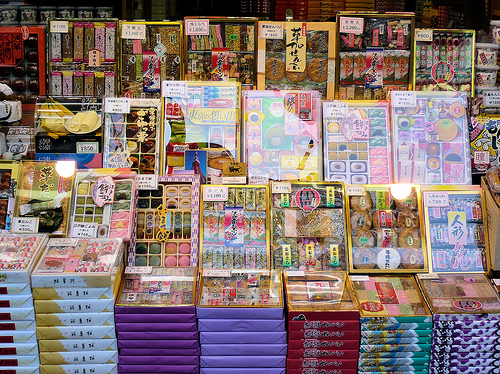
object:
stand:
[0, 1, 499, 372]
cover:
[283, 270, 359, 312]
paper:
[114, 303, 196, 314]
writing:
[285, 26, 304, 70]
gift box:
[180, 14, 258, 91]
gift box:
[256, 21, 337, 100]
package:
[117, 19, 184, 100]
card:
[183, 148, 208, 184]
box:
[34, 94, 106, 169]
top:
[259, 25, 334, 99]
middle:
[241, 89, 324, 180]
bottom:
[269, 181, 350, 271]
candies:
[80, 111, 99, 131]